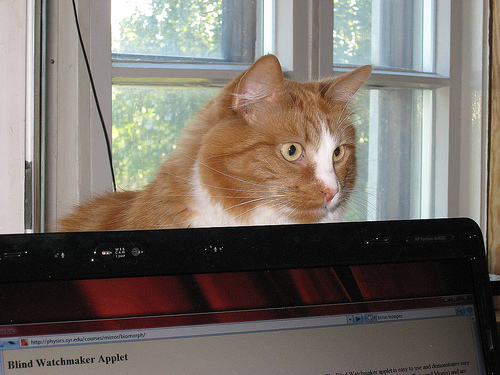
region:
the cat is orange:
[88, 54, 436, 297]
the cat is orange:
[171, 25, 343, 193]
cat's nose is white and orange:
[304, 118, 351, 213]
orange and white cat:
[48, 36, 460, 220]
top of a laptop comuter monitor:
[1, 210, 499, 372]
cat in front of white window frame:
[60, 0, 499, 211]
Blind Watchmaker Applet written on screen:
[2, 348, 137, 373]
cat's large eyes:
[271, 133, 354, 170]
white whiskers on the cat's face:
[185, 176, 296, 214]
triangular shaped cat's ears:
[216, 50, 381, 118]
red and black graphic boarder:
[53, 276, 281, 311]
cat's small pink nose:
[320, 181, 341, 204]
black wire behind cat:
[66, 14, 113, 149]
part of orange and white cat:
[52, 52, 377, 233]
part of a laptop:
[1, 215, 498, 373]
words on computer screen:
[1, 351, 133, 373]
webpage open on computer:
[0, 292, 488, 374]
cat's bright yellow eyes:
[277, 135, 347, 163]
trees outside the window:
[110, 83, 224, 193]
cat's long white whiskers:
[172, 157, 289, 212]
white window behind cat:
[73, 0, 464, 232]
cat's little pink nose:
[317, 184, 338, 203]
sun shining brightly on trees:
[110, 0, 224, 57]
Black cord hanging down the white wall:
[66, 0, 121, 193]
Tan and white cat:
[62, 52, 374, 227]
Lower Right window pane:
[110, 76, 229, 193]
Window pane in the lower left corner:
[332, 80, 441, 222]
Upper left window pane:
[334, 1, 439, 74]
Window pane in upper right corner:
[111, 0, 253, 62]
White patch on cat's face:
[315, 119, 337, 189]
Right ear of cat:
[221, 52, 287, 112]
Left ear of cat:
[322, 63, 372, 104]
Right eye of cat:
[275, 135, 306, 165]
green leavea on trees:
[110, 1, 375, 203]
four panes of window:
[90, 1, 457, 226]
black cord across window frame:
[74, 1, 113, 191]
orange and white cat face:
[209, 55, 376, 220]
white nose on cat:
[312, 133, 342, 193]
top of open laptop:
[5, 218, 489, 372]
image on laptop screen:
[3, 259, 485, 371]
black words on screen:
[7, 351, 129, 371]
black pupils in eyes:
[285, 143, 342, 158]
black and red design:
[0, 258, 474, 339]